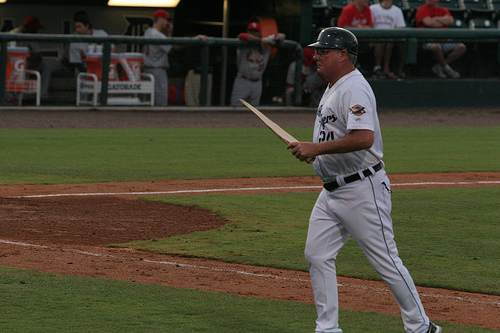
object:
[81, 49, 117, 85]
container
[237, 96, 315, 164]
wood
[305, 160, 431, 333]
pants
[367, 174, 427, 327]
stripe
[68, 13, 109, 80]
player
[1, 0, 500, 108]
dugout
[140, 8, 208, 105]
player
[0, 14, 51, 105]
player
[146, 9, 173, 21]
cap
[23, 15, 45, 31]
cap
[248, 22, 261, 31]
cap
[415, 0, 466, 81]
person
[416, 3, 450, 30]
shirt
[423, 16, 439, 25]
arms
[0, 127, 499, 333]
soil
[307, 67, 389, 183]
24 shirt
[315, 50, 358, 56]
goggles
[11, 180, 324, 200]
strip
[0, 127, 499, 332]
pitch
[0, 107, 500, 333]
field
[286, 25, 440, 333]
baseball player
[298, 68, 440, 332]
costume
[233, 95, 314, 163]
bat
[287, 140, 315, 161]
hand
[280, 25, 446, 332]
man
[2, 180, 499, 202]
white chalk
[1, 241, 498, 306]
white chalk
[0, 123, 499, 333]
baseball diamond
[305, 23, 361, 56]
helmet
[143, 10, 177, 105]
man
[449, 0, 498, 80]
crowd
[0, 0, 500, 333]
daytime picture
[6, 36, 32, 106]
cans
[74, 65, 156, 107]
trolley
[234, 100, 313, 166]
stake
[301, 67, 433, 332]
dress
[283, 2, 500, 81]
spectators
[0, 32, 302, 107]
metal bar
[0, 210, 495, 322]
lines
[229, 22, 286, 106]
player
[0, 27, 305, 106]
rail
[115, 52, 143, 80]
cooler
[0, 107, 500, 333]
grass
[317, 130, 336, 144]
24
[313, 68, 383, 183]
shirt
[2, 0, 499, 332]
baseball game